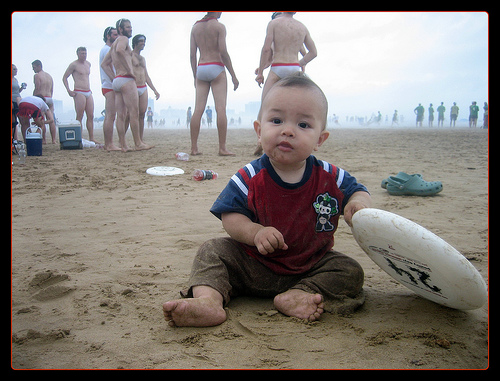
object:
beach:
[0, 127, 489, 366]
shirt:
[210, 153, 370, 276]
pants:
[178, 236, 366, 305]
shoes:
[380, 171, 444, 198]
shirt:
[20, 96, 47, 112]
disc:
[146, 166, 184, 175]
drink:
[193, 172, 217, 180]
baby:
[162, 70, 372, 330]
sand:
[11, 125, 489, 365]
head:
[253, 74, 329, 165]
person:
[253, 11, 317, 160]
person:
[129, 32, 159, 146]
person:
[63, 46, 99, 144]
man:
[188, 6, 240, 156]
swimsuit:
[192, 61, 227, 82]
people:
[0, 1, 328, 156]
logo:
[384, 250, 444, 294]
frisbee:
[350, 207, 488, 314]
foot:
[161, 294, 225, 328]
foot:
[272, 291, 326, 323]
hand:
[254, 225, 289, 254]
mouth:
[276, 140, 296, 152]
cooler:
[58, 119, 84, 149]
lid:
[57, 123, 81, 127]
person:
[18, 96, 54, 148]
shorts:
[15, 103, 43, 119]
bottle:
[191, 170, 218, 181]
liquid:
[194, 169, 218, 181]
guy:
[99, 16, 148, 152]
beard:
[122, 29, 132, 38]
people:
[184, 103, 490, 133]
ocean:
[47, 96, 486, 125]